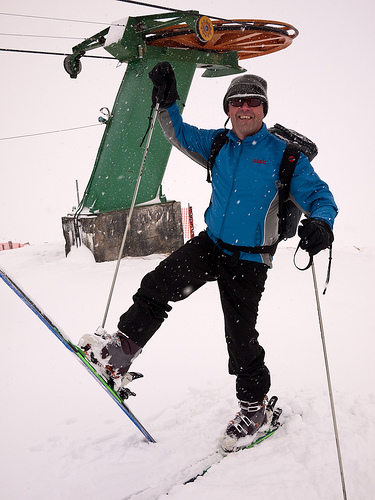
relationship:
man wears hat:
[78, 61, 338, 452] [219, 73, 268, 117]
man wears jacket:
[78, 61, 338, 452] [156, 102, 337, 270]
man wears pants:
[78, 61, 338, 452] [116, 229, 277, 401]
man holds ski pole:
[78, 43, 339, 446] [301, 250, 346, 494]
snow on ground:
[1, 237, 374, 497] [2, 222, 373, 498]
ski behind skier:
[59, 5, 301, 203] [79, 54, 347, 458]